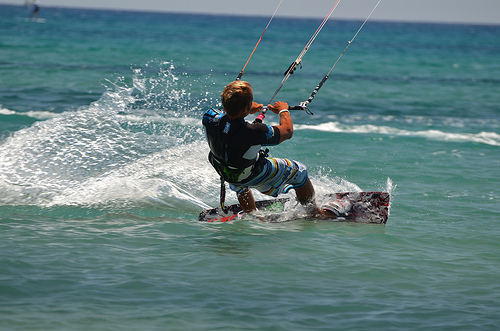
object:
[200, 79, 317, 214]
boarder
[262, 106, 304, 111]
bar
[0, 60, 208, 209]
spray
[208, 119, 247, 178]
best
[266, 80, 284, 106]
rope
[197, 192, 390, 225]
board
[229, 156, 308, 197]
shorts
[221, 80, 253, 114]
hair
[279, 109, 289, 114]
wristband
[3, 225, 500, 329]
ocean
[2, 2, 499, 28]
sky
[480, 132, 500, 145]
waves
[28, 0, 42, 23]
surfer